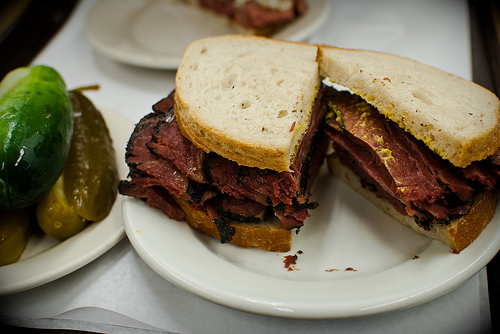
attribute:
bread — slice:
[173, 32, 320, 172]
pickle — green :
[13, 77, 65, 182]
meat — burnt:
[117, 92, 294, 226]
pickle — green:
[0, 72, 70, 267]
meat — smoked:
[139, 143, 273, 210]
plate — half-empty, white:
[81, 2, 331, 73]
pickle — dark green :
[65, 86, 114, 221]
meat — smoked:
[122, 87, 334, 234]